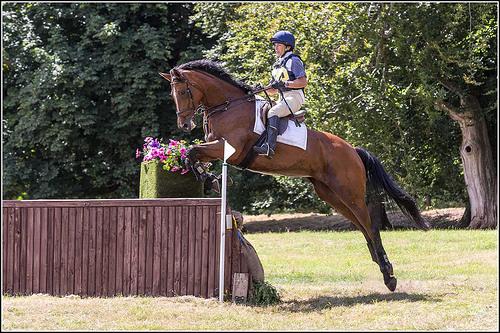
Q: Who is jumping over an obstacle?
A: An equestrian.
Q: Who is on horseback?
A: An equestrian.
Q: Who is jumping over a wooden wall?
A: A horse.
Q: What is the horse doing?
A: Jumping over an obstacle.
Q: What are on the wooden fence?
A: Flowers.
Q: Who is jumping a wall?
A: Horseback rider.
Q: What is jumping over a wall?
A: A horse.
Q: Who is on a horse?
A: Horseback rider.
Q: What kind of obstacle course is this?
A: Horse and rider.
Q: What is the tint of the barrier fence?
A: Brown wood.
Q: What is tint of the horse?
A: Brown and black.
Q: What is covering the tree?
A: Green leaves.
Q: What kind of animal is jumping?
A: A horse.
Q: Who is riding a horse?
A: A girl.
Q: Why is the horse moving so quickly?
A: To jump.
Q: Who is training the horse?
A: The rider.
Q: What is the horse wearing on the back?
A: A saddle.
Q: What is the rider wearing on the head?
A: A helmet.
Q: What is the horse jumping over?
A: A fence.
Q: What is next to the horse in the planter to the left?
A: Flowers.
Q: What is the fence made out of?
A: Wood.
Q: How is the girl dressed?
A: Like an equestrian.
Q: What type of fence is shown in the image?
A: A wooden equestrian fence.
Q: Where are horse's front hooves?
A: Over the barrier fence.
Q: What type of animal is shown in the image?
A: Brown horse.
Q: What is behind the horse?
A: A brown tree trunk.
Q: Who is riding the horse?
A: A person in blue and cream outfit.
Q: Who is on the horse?
A: A jockey.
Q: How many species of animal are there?
A: 2.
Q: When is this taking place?
A: Daytime.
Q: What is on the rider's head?
A: Helmet.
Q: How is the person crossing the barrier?
A: By horse.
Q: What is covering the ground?
A: Grass.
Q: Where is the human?
A: On the horse.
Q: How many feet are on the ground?
A: 0.